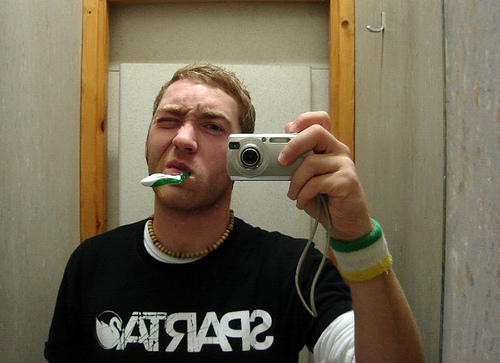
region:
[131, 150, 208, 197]
green and white toothbrush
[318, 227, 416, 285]
green white and yellow wristband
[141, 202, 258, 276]
necklace around his neck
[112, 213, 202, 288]
white shirt under black one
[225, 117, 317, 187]
a camera being held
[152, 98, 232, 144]
one eye is closed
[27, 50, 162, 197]
wood door frame behind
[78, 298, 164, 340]
black shirt with white lettering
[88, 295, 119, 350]
swan used as logo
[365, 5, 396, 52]
a hook on the wall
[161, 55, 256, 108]
Man has short hair.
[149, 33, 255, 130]
Man has light brown hair.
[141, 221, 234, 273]
Brown necklace around man's neck.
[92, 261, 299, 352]
Man wearing black shirt.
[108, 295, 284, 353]
White writing on shirt.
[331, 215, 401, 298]
Sweat band around man's wrist.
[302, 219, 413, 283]
Sweat band is green, white, and yellow.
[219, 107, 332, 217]
Man holding silver camera in hand.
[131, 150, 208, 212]
Toothbrush in man's mouth.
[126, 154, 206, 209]
Toothbrush is green and white.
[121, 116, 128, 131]
man taking selfie in mirror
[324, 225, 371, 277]
wristband is white and yellow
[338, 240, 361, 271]
wristband is green and white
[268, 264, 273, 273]
man wearing black shirt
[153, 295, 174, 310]
shirt is black and white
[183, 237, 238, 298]
man wearing brown necklace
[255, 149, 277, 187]
man holding gray camera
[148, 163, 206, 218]
green and white toothbrush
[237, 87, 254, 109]
man has brown hair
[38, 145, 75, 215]
wall behind man is gray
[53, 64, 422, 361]
man holding camera in fingers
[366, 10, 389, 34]
metal hook on wall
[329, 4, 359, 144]
wood frame on wall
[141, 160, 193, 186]
toothbrush in man's mouth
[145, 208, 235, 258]
beads on man's neck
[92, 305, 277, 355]
white logo on black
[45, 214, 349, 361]
black short sleeved shirt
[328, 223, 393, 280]
band on man's wrist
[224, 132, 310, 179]
silver camera with black lens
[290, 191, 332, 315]
handle hanging from wrist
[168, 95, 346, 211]
The man is talking a selfie.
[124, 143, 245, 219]
The man has a toothbrush in his mouth.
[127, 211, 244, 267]
The man is wearing a beaded necklace.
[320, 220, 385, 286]
A wristband on the wrist.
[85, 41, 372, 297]
The man is standing in front of mirror.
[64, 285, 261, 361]
White writing on the t-shirt.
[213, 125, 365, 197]
The man is holding a camera in his hand.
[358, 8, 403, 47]
A hook on the wall.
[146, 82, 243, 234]
The man is frowning.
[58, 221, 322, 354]
The man is wearing a black shirt.